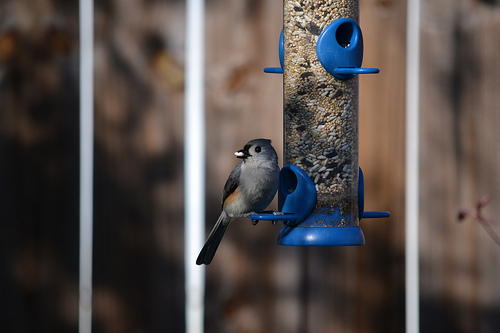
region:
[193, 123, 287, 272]
grey bird perched on edge of feeder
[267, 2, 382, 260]
feeder with blue trays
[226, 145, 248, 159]
white beak of bird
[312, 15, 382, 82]
blue feeding station of feeder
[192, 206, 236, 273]
grey tail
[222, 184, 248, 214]
red orange spot on grey bird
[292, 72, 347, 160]
bird feed inside feeder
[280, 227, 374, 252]
bottom of feeder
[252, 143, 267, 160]
black eye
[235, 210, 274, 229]
feet clutching side of blue feeder perch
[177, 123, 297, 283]
Grey bird eating seeds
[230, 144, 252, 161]
White seed in a black beak.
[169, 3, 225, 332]
White metal fence rail.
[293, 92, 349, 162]
Bird seed in a feeder.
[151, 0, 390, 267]
Bird on a bird feeder.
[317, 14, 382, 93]
Blue bird feeder perch.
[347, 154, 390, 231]
Blue bird feeder perch.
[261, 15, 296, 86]
Blue bird feeder perch.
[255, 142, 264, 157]
Black eye on a grey bird.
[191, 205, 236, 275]
Dark tail on a grey bird.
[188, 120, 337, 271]
little bird sitting on bird feeder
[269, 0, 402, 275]
bird feeder filled with bird feed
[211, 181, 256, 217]
little orange patch on bird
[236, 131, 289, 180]
bird with black eyes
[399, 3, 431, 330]
tall white poles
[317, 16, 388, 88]
plastic blue ledge on birdfeeder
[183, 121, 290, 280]
little bird looking to left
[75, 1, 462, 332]
three white poles behind bird feeder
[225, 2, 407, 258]
four plastic blue ledges on bird feeder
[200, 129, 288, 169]
bird with black and white beak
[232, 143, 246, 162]
beak of the bird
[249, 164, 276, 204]
chest of the bird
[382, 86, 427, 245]
part of a white post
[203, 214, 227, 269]
tail wing of the bird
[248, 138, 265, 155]
left eye of a bird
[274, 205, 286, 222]
left leg of the bird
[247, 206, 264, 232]
right leg of the bird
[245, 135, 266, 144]
head of the bird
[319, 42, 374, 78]
part of a blue holder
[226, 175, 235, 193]
wing of a bird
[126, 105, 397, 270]
bird perched on birdfeeder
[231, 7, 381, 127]
blue holes and curved hoops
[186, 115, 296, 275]
bird with head turned to side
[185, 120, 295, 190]
bird with seed in beak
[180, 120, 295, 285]
grey bird with black and orange markings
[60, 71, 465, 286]
white bars behind feeder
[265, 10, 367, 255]
container of round and oval seeds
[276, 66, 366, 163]
black, white and tan seeds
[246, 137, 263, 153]
round black eye on side of head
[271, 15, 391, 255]
transparent cylinder container holding seeds